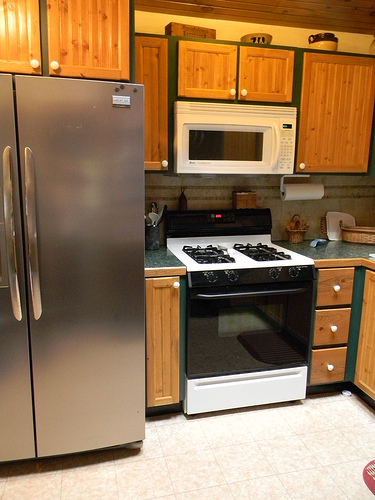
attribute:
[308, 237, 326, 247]
holder — blue, for spoon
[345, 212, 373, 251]
basket — brown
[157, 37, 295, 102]
wood cabinets — wooden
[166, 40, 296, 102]
cabinets — small, wooden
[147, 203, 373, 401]
drawers — wooden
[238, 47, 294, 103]
door — brown, cabinet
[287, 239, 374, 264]
countertop — green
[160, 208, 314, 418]
stove — gas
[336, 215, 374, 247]
basket — empty, wicker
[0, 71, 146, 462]
fridge — Stainless steel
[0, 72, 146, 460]
refigerator — steel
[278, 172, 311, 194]
dispenser — white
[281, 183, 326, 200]
towels — paper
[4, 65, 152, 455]
refrigerator — big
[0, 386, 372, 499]
floor — gray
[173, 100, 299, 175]
microwave — white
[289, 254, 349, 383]
drawers — small, wooden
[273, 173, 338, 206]
paper towel — white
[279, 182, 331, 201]
towels — paper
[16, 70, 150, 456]
door — of French